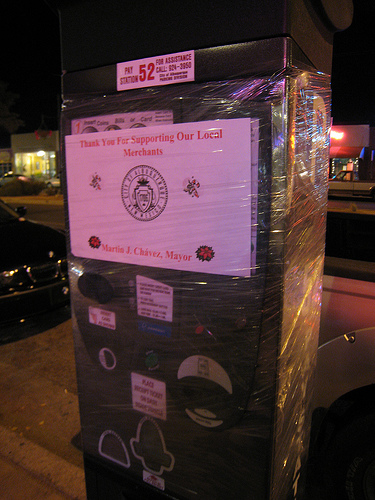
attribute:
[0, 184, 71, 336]
car — present, black, dark, parked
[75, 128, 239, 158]
writing — present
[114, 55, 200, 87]
writing — red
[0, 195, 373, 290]
road — present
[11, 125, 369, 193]
wall — white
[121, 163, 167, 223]
picture — small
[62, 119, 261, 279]
sign — white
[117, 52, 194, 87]
letter — red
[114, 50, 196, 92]
sign — white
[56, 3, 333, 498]
package — dark, 52, wrapped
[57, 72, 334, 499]
wrapping — clear, plastic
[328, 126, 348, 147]
light — red, glowing, on, neon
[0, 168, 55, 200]
car — parked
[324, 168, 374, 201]
car — parked, red, white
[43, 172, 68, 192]
car — white, blocked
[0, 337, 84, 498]
concrete — dirty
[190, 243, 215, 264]
drawing — christmas, poinsettia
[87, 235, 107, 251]
drawing — christmas, poinsettia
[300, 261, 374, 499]
car — silver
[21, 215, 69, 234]
line — white